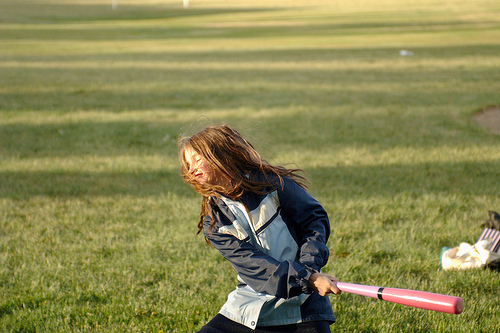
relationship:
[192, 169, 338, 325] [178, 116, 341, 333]
body of child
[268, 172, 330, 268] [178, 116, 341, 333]
arm of child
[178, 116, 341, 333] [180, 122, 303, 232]
child with hair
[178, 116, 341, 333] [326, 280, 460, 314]
child holding bat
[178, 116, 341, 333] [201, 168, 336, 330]
child wearing coat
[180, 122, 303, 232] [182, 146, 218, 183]
hair in face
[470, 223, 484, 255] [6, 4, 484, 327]
bag on ground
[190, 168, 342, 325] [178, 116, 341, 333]
coat of child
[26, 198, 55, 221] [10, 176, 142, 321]
sun on grass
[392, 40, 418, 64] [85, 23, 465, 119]
trash in park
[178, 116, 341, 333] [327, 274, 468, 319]
child swinging bat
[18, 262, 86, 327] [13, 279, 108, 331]
patch made of grass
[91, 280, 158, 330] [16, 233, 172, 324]
patch made of grass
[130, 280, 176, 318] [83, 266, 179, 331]
patch made of grass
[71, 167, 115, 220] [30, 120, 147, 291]
patch made of grass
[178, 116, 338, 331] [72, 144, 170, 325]
child in grass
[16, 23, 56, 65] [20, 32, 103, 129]
patch made of grass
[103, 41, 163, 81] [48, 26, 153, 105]
patch made of grass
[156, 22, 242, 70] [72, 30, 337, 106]
patch made of grass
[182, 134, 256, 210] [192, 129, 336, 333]
head of girl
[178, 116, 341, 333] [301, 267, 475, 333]
child swinging bat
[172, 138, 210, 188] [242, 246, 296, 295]
face of girl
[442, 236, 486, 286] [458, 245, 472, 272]
bundle of cloths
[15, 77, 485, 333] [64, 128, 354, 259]
grass covered field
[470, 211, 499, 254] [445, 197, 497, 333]
bag in grass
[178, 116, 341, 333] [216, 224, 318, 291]
child wearing a jacket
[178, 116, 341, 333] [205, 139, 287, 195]
child has hair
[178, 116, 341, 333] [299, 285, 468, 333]
child holding a bat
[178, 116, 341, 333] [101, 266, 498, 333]
child playing in grass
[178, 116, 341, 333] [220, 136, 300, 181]
child has hair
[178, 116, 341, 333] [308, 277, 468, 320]
child in grass playing with bat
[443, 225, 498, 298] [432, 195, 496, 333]
group of things on pitch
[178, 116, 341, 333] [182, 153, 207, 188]
child playing with closed eyes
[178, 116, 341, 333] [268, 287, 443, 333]
child  playing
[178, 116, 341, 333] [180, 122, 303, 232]
child has hair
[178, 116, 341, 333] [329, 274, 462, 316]
child has bat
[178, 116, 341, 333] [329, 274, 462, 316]
child swinging bat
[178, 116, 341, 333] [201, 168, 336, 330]
child in coat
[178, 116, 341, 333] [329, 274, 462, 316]
child holding bat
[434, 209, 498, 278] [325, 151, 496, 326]
stuff in grass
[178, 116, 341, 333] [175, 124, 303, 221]
child has hair